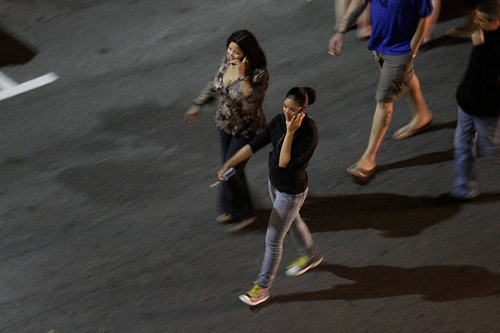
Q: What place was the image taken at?
A: It was taken at the road.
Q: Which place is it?
A: It is a road.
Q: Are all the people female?
A: No, they are both male and female.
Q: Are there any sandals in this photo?
A: Yes, there are sandals.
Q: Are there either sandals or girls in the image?
A: Yes, there are sandals.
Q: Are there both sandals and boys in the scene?
A: No, there are sandals but no boys.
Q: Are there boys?
A: No, there are no boys.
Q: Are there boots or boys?
A: No, there are no boys or boots.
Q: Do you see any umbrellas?
A: No, there are no umbrellas.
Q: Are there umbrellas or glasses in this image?
A: No, there are no umbrellas or glasses.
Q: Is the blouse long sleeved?
A: Yes, the blouse is long sleeved.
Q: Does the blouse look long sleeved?
A: Yes, the blouse is long sleeved.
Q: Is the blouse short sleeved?
A: No, the blouse is long sleeved.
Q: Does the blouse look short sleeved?
A: No, the blouse is long sleeved.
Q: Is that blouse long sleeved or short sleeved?
A: The blouse is long sleeved.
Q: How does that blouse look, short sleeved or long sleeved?
A: The blouse is long sleeved.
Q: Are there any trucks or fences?
A: No, there are no fences or trucks.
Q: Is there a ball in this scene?
A: No, there are no balls.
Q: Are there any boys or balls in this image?
A: No, there are no balls or boys.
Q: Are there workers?
A: No, there are no workers.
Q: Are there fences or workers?
A: No, there are no workers or fences.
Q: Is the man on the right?
A: Yes, the man is on the right of the image.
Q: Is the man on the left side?
A: No, the man is on the right of the image.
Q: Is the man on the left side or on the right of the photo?
A: The man is on the right of the image.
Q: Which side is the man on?
A: The man is on the right of the image.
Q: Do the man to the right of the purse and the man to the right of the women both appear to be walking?
A: Yes, both the man and the man are walking.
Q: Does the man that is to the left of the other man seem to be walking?
A: Yes, the man is walking.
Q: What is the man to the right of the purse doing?
A: The man is walking.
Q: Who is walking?
A: The man is walking.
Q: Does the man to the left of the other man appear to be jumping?
A: No, the man is walking.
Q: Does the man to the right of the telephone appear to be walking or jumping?
A: The man is walking.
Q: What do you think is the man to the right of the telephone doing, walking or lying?
A: The man is walking.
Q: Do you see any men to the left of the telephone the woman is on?
A: No, the man is to the right of the telephone.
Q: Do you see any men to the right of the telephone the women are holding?
A: Yes, there is a man to the right of the phone.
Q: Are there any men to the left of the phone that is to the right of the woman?
A: No, the man is to the right of the telephone.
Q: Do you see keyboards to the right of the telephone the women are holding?
A: No, there is a man to the right of the phone.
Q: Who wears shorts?
A: The man wears shorts.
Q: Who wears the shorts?
A: The man wears shorts.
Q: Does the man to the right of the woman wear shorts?
A: Yes, the man wears shorts.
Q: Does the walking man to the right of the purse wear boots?
A: No, the man wears shorts.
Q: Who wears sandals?
A: The man wears sandals.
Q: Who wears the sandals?
A: The man wears sandals.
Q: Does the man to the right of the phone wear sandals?
A: Yes, the man wears sandals.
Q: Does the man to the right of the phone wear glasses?
A: No, the man wears sandals.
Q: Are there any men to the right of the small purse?
A: Yes, there is a man to the right of the purse.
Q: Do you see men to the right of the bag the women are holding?
A: Yes, there is a man to the right of the purse.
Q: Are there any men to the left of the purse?
A: No, the man is to the right of the purse.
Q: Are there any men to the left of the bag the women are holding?
A: No, the man is to the right of the purse.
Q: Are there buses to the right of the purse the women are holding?
A: No, there is a man to the right of the purse.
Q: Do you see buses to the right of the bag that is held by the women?
A: No, there is a man to the right of the purse.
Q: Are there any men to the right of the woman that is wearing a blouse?
A: Yes, there is a man to the right of the woman.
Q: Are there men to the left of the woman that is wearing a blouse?
A: No, the man is to the right of the woman.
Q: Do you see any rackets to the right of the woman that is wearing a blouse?
A: No, there is a man to the right of the woman.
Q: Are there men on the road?
A: Yes, there is a man on the road.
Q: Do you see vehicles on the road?
A: No, there is a man on the road.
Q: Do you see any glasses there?
A: No, there are no glasses.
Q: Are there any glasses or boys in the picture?
A: No, there are no glasses or boys.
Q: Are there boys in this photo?
A: No, there are no boys.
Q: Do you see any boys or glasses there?
A: No, there are no boys or glasses.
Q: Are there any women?
A: Yes, there is a woman.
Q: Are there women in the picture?
A: Yes, there is a woman.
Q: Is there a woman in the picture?
A: Yes, there is a woman.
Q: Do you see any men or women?
A: Yes, there is a woman.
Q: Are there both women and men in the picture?
A: Yes, there are both a woman and a man.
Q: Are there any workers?
A: No, there are no workers.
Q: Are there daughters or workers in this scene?
A: No, there are no workers or daughters.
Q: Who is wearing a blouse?
A: The woman is wearing a blouse.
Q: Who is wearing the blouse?
A: The woman is wearing a blouse.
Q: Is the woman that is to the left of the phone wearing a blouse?
A: Yes, the woman is wearing a blouse.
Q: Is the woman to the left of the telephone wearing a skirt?
A: No, the woman is wearing a blouse.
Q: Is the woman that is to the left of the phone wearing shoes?
A: Yes, the woman is wearing shoes.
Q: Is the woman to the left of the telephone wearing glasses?
A: No, the woman is wearing shoes.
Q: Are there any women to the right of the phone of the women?
A: No, the woman is to the left of the phone.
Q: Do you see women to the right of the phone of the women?
A: No, the woman is to the left of the phone.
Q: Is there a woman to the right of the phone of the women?
A: No, the woman is to the left of the phone.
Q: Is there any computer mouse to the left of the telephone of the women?
A: No, there is a woman to the left of the phone.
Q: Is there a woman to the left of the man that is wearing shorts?
A: Yes, there is a woman to the left of the man.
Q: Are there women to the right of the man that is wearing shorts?
A: No, the woman is to the left of the man.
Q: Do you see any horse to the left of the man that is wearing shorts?
A: No, there is a woman to the left of the man.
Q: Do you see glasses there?
A: No, there are no glasses.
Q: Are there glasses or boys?
A: No, there are no glasses or boys.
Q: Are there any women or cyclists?
A: Yes, there are women.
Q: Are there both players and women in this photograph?
A: No, there are women but no players.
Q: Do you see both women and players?
A: No, there are women but no players.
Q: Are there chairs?
A: No, there are no chairs.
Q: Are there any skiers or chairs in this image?
A: No, there are no chairs or skiers.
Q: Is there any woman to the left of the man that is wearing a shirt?
A: Yes, there are women to the left of the man.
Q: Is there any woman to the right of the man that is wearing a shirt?
A: No, the women are to the left of the man.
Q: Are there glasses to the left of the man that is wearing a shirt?
A: No, there are women to the left of the man.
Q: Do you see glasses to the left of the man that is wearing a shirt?
A: No, there are women to the left of the man.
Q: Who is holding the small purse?
A: The women are holding the purse.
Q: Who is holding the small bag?
A: The women are holding the purse.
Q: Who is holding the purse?
A: The women are holding the purse.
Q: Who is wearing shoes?
A: The women are wearing shoes.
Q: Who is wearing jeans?
A: The women are wearing jeans.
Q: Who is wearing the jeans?
A: The women are wearing jeans.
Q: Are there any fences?
A: No, there are no fences.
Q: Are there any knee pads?
A: No, there are no knee pads.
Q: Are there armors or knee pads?
A: No, there are no knee pads or armors.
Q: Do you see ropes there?
A: No, there are no ropes.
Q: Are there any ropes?
A: No, there are no ropes.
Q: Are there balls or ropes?
A: No, there are no ropes or balls.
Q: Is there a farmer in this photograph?
A: No, there are no farmers.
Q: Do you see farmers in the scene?
A: No, there are no farmers.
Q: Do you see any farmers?
A: No, there are no farmers.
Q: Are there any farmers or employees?
A: No, there are no farmers or employees.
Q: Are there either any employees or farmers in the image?
A: No, there are no farmers or employees.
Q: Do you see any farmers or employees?
A: No, there are no farmers or employees.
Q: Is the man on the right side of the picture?
A: Yes, the man is on the right of the image.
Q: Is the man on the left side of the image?
A: No, the man is on the right of the image.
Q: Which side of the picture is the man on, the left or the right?
A: The man is on the right of the image.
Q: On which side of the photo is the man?
A: The man is on the right of the image.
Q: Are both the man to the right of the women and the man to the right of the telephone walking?
A: Yes, both the man and the man are walking.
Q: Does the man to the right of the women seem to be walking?
A: Yes, the man is walking.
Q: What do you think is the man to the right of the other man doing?
A: The man is walking.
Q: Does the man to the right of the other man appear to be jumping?
A: No, the man is walking.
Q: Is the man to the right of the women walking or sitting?
A: The man is walking.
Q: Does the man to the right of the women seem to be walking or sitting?
A: The man is walking.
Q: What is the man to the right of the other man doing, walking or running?
A: The man is walking.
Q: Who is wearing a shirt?
A: The man is wearing a shirt.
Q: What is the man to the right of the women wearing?
A: The man is wearing a shirt.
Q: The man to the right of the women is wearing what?
A: The man is wearing a shirt.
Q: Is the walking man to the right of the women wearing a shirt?
A: Yes, the man is wearing a shirt.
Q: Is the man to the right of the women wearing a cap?
A: No, the man is wearing a shirt.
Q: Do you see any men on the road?
A: Yes, there is a man on the road.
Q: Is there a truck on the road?
A: No, there is a man on the road.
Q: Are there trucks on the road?
A: No, there is a man on the road.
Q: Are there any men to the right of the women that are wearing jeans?
A: Yes, there is a man to the right of the women.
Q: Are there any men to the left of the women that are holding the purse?
A: No, the man is to the right of the women.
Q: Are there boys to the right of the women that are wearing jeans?
A: No, there is a man to the right of the women.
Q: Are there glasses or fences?
A: No, there are no fences or glasses.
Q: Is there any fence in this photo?
A: No, there are no fences.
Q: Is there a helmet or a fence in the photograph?
A: No, there are no fences or helmets.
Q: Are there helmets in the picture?
A: No, there are no helmets.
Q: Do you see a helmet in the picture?
A: No, there are no helmets.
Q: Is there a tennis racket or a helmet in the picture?
A: No, there are no helmets or rackets.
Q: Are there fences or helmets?
A: No, there are no fences or helmets.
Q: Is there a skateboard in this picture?
A: No, there are no skateboards.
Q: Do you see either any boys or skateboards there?
A: No, there are no skateboards or boys.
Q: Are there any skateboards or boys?
A: No, there are no skateboards or boys.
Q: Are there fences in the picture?
A: No, there are no fences.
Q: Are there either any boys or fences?
A: No, there are no fences or boys.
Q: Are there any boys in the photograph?
A: No, there are no boys.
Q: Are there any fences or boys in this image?
A: No, there are no boys or fences.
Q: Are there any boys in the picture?
A: No, there are no boys.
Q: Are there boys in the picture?
A: No, there are no boys.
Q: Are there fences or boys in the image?
A: No, there are no boys or fences.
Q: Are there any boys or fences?
A: No, there are no boys or fences.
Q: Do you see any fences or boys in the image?
A: No, there are no boys or fences.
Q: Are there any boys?
A: No, there are no boys.